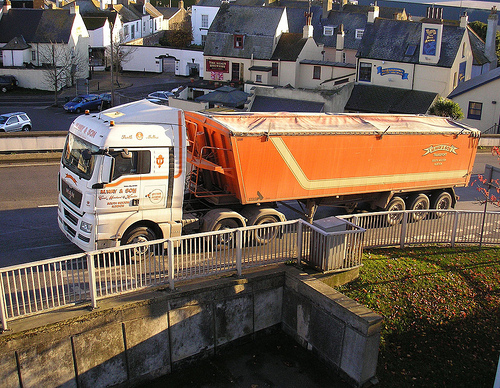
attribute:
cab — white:
[86, 102, 187, 233]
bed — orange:
[213, 112, 471, 189]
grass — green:
[380, 257, 436, 313]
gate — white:
[73, 248, 206, 286]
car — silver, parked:
[1, 108, 32, 136]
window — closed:
[302, 59, 328, 82]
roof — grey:
[244, 8, 282, 59]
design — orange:
[145, 148, 173, 171]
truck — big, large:
[66, 115, 499, 208]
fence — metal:
[19, 268, 96, 304]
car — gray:
[63, 101, 127, 120]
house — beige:
[473, 68, 499, 135]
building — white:
[186, 7, 212, 41]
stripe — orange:
[102, 174, 162, 183]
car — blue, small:
[144, 79, 173, 101]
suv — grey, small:
[10, 112, 33, 131]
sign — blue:
[426, 20, 437, 67]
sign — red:
[203, 54, 232, 73]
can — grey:
[320, 205, 352, 271]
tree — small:
[474, 174, 494, 246]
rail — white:
[83, 236, 166, 256]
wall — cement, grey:
[67, 300, 230, 365]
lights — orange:
[82, 110, 118, 136]